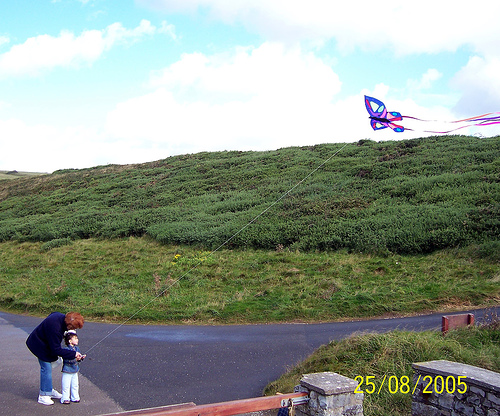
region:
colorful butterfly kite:
[362, 91, 411, 136]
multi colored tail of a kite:
[405, 110, 499, 136]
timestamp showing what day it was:
[350, 373, 466, 395]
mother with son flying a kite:
[22, 296, 94, 406]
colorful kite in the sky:
[362, 93, 497, 148]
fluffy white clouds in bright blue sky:
[11, 16, 368, 110]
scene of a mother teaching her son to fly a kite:
[8, 16, 487, 413]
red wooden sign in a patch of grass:
[440, 308, 479, 338]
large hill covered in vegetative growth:
[27, 143, 444, 275]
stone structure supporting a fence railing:
[299, 364, 356, 414]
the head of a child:
[61, 331, 83, 344]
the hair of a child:
[64, 330, 71, 339]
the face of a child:
[71, 335, 81, 345]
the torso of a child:
[59, 345, 76, 368]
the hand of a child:
[78, 352, 88, 359]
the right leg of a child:
[53, 367, 72, 399]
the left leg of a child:
[69, 374, 85, 401]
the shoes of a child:
[59, 397, 84, 404]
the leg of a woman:
[28, 362, 57, 395]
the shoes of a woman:
[36, 384, 57, 404]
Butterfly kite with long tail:
[357, 91, 497, 146]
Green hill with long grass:
[9, 134, 497, 317]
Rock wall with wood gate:
[96, 373, 365, 415]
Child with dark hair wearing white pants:
[57, 331, 87, 406]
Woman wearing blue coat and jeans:
[26, 308, 85, 405]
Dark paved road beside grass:
[1, 304, 498, 411]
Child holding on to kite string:
[27, 87, 498, 405]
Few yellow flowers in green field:
[10, 137, 496, 312]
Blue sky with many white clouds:
[0, 4, 498, 176]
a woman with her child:
[24, 294, 94, 412]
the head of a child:
[60, 331, 87, 346]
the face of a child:
[69, 337, 79, 346]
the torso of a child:
[64, 344, 80, 366]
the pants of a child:
[57, 370, 86, 397]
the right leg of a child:
[60, 369, 72, 398]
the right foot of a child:
[60, 396, 71, 406]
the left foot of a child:
[72, 397, 84, 409]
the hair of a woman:
[65, 312, 84, 328]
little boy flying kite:
[58, 332, 91, 404]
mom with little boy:
[21, 308, 53, 397]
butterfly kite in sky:
[337, 85, 426, 145]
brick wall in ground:
[445, 311, 472, 338]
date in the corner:
[343, 366, 467, 399]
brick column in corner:
[301, 366, 366, 411]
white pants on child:
[58, 369, 78, 406]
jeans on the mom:
[37, 357, 58, 394]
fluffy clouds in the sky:
[8, 32, 100, 67]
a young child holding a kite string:
[60, 331, 100, 406]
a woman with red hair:
[62, 307, 84, 332]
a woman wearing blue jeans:
[33, 358, 59, 406]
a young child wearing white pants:
[60, 367, 82, 407]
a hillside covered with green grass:
[49, 148, 292, 238]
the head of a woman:
[66, 310, 85, 329]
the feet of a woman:
[36, 386, 64, 406]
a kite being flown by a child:
[355, 79, 494, 146]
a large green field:
[1, 134, 498, 325]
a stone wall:
[408, 358, 498, 414]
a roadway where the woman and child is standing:
[6, 287, 498, 414]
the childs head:
[66, 334, 81, 345]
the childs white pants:
[58, 372, 85, 407]